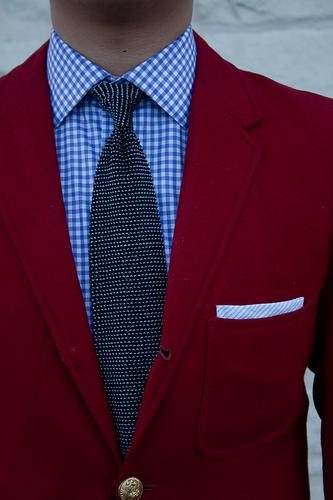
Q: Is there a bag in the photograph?
A: No, there are no bags.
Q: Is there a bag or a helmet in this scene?
A: No, there are no bags or helmets.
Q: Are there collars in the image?
A: Yes, there is a collar.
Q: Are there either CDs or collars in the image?
A: Yes, there is a collar.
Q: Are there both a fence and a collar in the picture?
A: No, there is a collar but no fences.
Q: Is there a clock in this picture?
A: No, there are no clocks.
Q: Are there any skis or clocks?
A: No, there are no clocks or skis.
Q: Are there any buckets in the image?
A: No, there are no buckets.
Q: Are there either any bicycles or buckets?
A: No, there are no buckets or bicycles.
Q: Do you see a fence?
A: No, there are no fences.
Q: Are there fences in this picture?
A: No, there are no fences.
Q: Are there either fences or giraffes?
A: No, there are no fences or giraffes.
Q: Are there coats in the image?
A: Yes, there is a coat.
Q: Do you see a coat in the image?
A: Yes, there is a coat.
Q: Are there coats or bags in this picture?
A: Yes, there is a coat.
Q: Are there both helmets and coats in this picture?
A: No, there is a coat but no helmets.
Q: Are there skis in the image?
A: No, there are no skis.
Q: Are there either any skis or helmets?
A: No, there are no skis or helmets.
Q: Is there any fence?
A: No, there are no fences.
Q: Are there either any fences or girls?
A: No, there are no fences or girls.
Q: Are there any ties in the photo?
A: Yes, there is a tie.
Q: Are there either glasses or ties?
A: Yes, there is a tie.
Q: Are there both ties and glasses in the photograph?
A: No, there is a tie but no glasses.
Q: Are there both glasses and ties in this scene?
A: No, there is a tie but no glasses.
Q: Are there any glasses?
A: No, there are no glasses.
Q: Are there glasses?
A: No, there are no glasses.